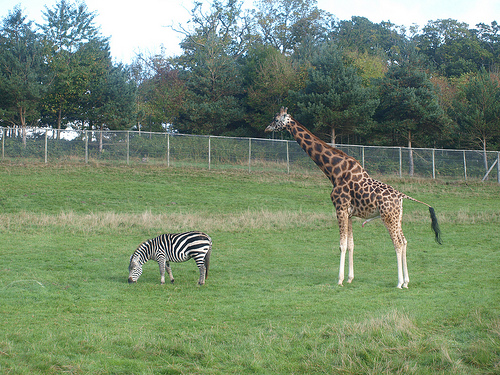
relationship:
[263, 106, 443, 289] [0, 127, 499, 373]
giraffe in enclosure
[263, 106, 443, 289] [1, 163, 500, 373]
giraffe in field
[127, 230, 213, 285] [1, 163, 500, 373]
zebra in field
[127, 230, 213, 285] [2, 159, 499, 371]
zebra eating grass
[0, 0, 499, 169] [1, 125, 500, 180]
trees near fence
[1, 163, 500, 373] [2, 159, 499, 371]
field of grass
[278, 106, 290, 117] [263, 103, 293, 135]
horns on head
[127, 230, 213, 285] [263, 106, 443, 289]
zebra in front of giraffe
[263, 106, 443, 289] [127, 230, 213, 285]
giraffe sees zebra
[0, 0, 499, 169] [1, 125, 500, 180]
trees behind fence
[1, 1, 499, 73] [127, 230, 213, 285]
sky above zebra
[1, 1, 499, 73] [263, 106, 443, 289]
sky above giraffe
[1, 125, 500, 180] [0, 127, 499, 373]
fence for enclosure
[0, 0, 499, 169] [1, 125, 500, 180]
trees along fence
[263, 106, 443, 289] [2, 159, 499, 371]
giraffe on grass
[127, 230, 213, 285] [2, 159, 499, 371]
zebra grazing on grass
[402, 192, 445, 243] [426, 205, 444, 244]
tail with hair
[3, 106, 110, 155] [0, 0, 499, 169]
trunks of trees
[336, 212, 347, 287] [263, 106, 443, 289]
leg of giraffe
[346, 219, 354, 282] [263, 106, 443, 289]
leg of giraffe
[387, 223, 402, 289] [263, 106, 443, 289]
leg of giraffe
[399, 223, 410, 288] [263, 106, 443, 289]
leg of giraffe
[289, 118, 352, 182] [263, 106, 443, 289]
neck of giraffe